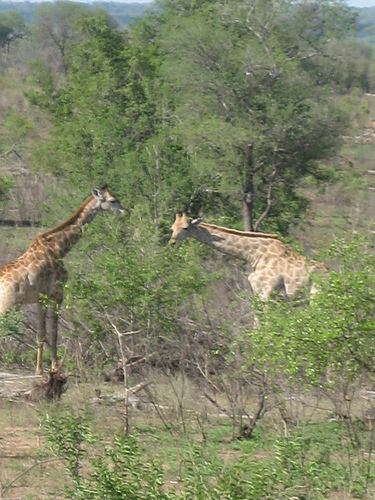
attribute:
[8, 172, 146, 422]
adult giraffe — dark orange, big, dark colored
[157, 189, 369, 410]
adult giraffe — light orange, light colored, facing front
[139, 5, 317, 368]
tree — tall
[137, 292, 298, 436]
bush — leafless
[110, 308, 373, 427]
tree — dead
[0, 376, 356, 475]
ground — dry, here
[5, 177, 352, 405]
two giraffes — here, grazing, standing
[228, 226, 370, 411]
bush — leafy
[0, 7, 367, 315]
trees — here, dead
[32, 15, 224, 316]
tree — healthy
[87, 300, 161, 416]
branches — here, dead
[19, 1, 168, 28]
sky — blue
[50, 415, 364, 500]
shrubs — here, dry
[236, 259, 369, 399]
leaves — green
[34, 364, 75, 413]
trunk — fallen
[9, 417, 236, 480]
grass — arid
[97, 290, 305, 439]
plants — dry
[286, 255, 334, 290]
front hip — here